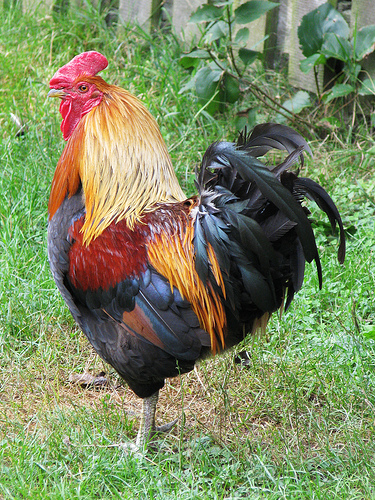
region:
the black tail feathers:
[189, 120, 337, 304]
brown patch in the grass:
[22, 345, 84, 445]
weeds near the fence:
[193, 0, 357, 138]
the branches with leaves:
[227, 54, 336, 119]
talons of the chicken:
[115, 415, 185, 467]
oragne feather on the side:
[159, 238, 234, 333]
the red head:
[38, 47, 116, 138]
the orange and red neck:
[58, 115, 188, 213]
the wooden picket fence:
[133, 0, 309, 61]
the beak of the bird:
[44, 82, 71, 103]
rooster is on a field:
[25, 36, 360, 469]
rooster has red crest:
[32, 35, 116, 97]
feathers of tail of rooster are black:
[216, 109, 355, 291]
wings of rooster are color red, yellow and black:
[62, 202, 235, 348]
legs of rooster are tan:
[117, 395, 178, 465]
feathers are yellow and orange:
[42, 100, 183, 218]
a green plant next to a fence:
[170, 7, 373, 135]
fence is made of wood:
[16, 1, 373, 68]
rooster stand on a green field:
[2, 34, 370, 497]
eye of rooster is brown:
[73, 77, 90, 96]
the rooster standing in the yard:
[43, 48, 327, 474]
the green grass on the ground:
[6, 10, 367, 486]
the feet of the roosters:
[65, 363, 179, 470]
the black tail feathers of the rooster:
[186, 126, 353, 309]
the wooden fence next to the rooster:
[20, 3, 373, 139]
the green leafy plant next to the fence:
[172, 6, 373, 161]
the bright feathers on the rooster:
[49, 91, 201, 282]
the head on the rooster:
[41, 56, 105, 132]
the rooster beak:
[43, 88, 62, 99]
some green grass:
[40, 420, 161, 499]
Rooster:
[15, 30, 331, 399]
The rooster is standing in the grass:
[27, 42, 336, 479]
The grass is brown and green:
[19, 341, 346, 480]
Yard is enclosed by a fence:
[80, 3, 362, 82]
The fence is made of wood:
[122, 2, 364, 75]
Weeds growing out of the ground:
[175, 12, 368, 138]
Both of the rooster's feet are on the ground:
[55, 351, 200, 464]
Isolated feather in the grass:
[1, 99, 37, 144]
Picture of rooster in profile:
[34, 47, 161, 172]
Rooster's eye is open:
[70, 76, 97, 99]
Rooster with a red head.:
[30, 42, 140, 131]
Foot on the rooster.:
[85, 379, 203, 464]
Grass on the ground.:
[73, 413, 191, 479]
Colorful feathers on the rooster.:
[49, 92, 288, 341]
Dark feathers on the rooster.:
[184, 131, 310, 282]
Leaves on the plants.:
[178, 13, 277, 141]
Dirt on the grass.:
[139, 385, 285, 443]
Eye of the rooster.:
[56, 58, 108, 102]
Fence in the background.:
[169, 6, 313, 102]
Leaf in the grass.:
[9, 107, 45, 154]